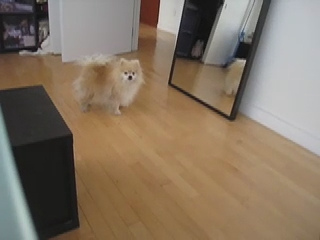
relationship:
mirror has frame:
[168, 1, 270, 119] [168, 1, 270, 120]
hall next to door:
[138, 0, 183, 51] [58, 1, 136, 64]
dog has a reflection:
[73, 54, 146, 116] [221, 58, 249, 97]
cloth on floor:
[20, 35, 63, 57] [1, 22, 320, 240]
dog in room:
[73, 54, 146, 116] [2, 0, 320, 239]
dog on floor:
[73, 54, 146, 116] [1, 22, 320, 240]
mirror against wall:
[168, 1, 270, 119] [174, 0, 319, 158]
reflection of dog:
[221, 58, 249, 97] [73, 54, 146, 116]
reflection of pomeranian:
[221, 58, 249, 97] [73, 54, 146, 116]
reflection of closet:
[177, 0, 250, 66] [174, 0, 255, 68]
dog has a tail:
[73, 54, 146, 116] [74, 52, 108, 99]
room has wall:
[2, 0, 320, 239] [174, 0, 319, 158]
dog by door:
[73, 54, 146, 116] [58, 1, 136, 64]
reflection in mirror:
[221, 58, 249, 97] [168, 1, 270, 119]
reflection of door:
[201, 1, 247, 66] [200, 1, 248, 66]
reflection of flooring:
[171, 58, 240, 116] [1, 22, 320, 240]